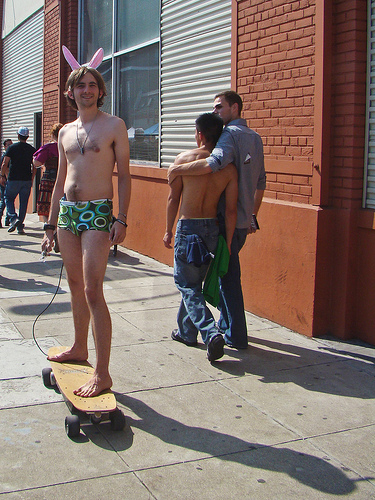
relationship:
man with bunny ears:
[39, 45, 131, 439] [61, 41, 106, 71]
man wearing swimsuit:
[39, 45, 131, 439] [56, 195, 112, 236]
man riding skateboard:
[39, 45, 131, 439] [42, 346, 126, 438]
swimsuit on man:
[56, 195, 112, 236] [39, 45, 131, 439]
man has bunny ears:
[39, 45, 131, 439] [61, 41, 106, 71]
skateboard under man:
[42, 346, 126, 438] [39, 45, 131, 439]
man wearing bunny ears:
[39, 45, 131, 439] [61, 41, 106, 71]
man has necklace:
[39, 45, 131, 439] [75, 109, 100, 156]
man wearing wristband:
[39, 45, 131, 439] [116, 217, 128, 227]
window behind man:
[78, 2, 160, 166] [39, 45, 131, 439]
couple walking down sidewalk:
[163, 88, 269, 361] [0, 206, 373, 500]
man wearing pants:
[161, 115, 239, 360] [172, 218, 225, 360]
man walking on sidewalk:
[161, 115, 239, 360] [0, 206, 373, 500]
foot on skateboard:
[44, 349, 114, 397] [42, 346, 126, 438]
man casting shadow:
[39, 45, 131, 439] [111, 388, 356, 497]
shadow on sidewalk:
[111, 388, 356, 497] [0, 206, 373, 500]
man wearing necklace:
[39, 45, 131, 439] [75, 109, 100, 156]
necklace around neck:
[75, 109, 100, 156] [78, 99, 99, 120]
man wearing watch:
[39, 45, 131, 439] [42, 222, 56, 232]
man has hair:
[39, 45, 131, 439] [64, 67, 109, 108]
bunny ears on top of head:
[61, 41, 106, 71] [64, 67, 106, 109]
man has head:
[39, 45, 131, 439] [64, 67, 106, 109]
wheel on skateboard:
[64, 414, 81, 438] [42, 346, 126, 438]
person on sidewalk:
[1, 123, 40, 235] [0, 206, 373, 500]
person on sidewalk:
[30, 122, 65, 256] [0, 206, 373, 500]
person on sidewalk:
[163, 113, 240, 362] [0, 206, 373, 500]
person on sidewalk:
[167, 92, 265, 349] [0, 206, 373, 500]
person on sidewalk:
[40, 69, 132, 398] [0, 206, 373, 500]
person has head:
[167, 92, 265, 349] [213, 91, 243, 121]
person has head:
[163, 113, 240, 362] [195, 113, 223, 147]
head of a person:
[51, 123, 63, 143] [30, 122, 65, 256]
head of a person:
[64, 67, 106, 109] [40, 69, 132, 398]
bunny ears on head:
[61, 41, 106, 71] [64, 67, 106, 109]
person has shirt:
[167, 92, 265, 349] [204, 116, 266, 230]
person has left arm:
[167, 92, 265, 349] [167, 127, 239, 182]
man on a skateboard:
[39, 45, 131, 439] [42, 346, 126, 438]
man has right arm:
[39, 45, 131, 439] [41, 130, 68, 257]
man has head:
[161, 115, 239, 360] [195, 113, 223, 147]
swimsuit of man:
[56, 195, 112, 236] [39, 45, 131, 439]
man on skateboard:
[39, 45, 131, 439] [42, 346, 126, 438]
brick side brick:
[37, 0, 375, 347] [43, 1, 372, 338]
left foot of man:
[74, 369, 115, 397] [39, 45, 131, 439]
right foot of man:
[47, 343, 88, 363] [39, 45, 131, 439]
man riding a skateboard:
[39, 45, 131, 439] [42, 346, 126, 438]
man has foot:
[39, 45, 131, 439] [44, 349, 114, 397]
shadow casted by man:
[111, 388, 356, 497] [39, 45, 131, 439]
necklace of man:
[75, 109, 100, 156] [39, 45, 131, 439]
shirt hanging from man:
[202, 234, 229, 311] [161, 115, 239, 360]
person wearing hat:
[1, 123, 40, 235] [16, 127, 30, 137]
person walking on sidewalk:
[30, 122, 65, 256] [0, 206, 373, 500]